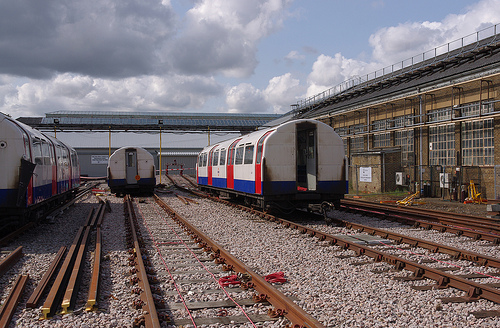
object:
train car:
[196, 118, 344, 195]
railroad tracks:
[312, 212, 498, 318]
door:
[306, 128, 316, 191]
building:
[285, 23, 499, 203]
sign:
[357, 166, 372, 181]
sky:
[2, 2, 267, 68]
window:
[243, 145, 253, 163]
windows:
[460, 98, 496, 167]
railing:
[21, 160, 38, 210]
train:
[196, 119, 344, 223]